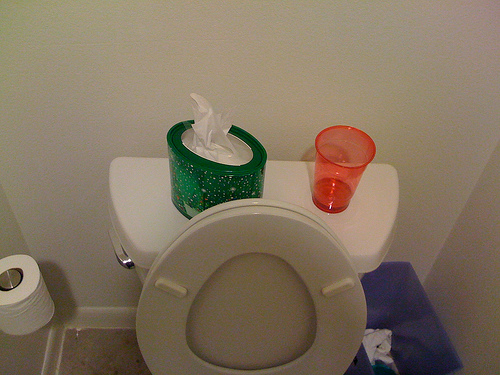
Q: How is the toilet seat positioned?
A: Up.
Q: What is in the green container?
A: Tissues.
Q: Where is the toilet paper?
A: On the wall.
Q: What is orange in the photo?
A: A cup.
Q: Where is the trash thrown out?
A: In blue basket.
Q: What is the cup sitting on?
A: Toilet tank.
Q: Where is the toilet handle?
A: Left of tank.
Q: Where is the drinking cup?
A: On the toilet.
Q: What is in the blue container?
A: Trash.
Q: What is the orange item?
A: Drinking cup.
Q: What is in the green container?
A: Tissue.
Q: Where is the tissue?
A: On the toilet.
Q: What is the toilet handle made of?
A: Metal.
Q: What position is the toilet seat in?
A: Up.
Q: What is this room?
A: Bathroom.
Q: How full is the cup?
A: It's empty.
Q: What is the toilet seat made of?
A: Plastic.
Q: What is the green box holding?
A: Tissue.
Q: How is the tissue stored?
A: In a box.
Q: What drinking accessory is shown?
A: A cup.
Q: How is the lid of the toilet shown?
A: Up.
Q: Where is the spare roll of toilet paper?
A: Against the wall.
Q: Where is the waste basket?
A: The floor.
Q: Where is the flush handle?
A: The side of the toilet.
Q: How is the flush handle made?
A: Of silver.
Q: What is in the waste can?
A: Tissue.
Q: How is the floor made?
A: Of tile.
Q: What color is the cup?
A: Orange.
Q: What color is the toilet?
A: White.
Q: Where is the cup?
A: On top of the toilet.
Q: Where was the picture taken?
A: A bathroom.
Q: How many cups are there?
A: One.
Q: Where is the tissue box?
A: To the left of the cup.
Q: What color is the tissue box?
A: Green.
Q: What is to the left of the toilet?
A: Toilet paper.